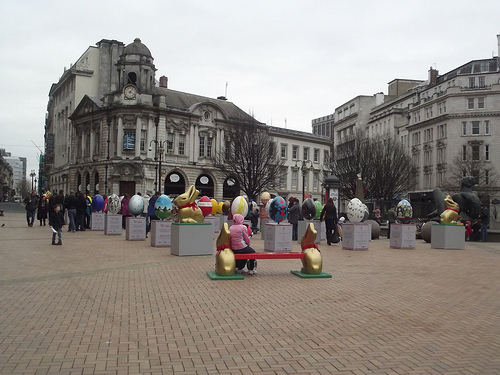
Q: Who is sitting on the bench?
A: A woman.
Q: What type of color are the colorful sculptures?
A: Eggs.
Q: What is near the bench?
A: Golden easter bunnies.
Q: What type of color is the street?
A: Gray.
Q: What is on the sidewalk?
A: Bricks.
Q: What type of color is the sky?
A: White.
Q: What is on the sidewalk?
A: Brick.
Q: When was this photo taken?
A: Outside, during the daytime.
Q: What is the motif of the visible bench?
A: Chocolate bunnies.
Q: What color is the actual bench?
A: Red.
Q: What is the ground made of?
A: Bricks.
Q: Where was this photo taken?
A: At an Easter exhibit.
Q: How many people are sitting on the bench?
A: One.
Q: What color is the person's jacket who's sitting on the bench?
A: Pink.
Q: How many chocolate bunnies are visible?
A: Four.